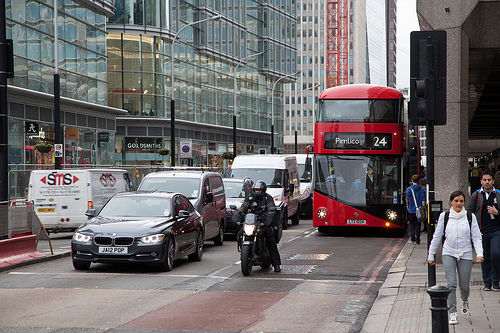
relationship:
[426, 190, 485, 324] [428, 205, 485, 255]
lady wearing jacket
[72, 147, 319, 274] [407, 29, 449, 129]
row parked at traffic light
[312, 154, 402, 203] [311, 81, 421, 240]
window on front of bus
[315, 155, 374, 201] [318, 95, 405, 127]
reflection in window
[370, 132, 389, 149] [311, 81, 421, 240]
number on bus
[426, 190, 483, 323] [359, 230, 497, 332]
lady on sidewalk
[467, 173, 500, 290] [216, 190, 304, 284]
man on bike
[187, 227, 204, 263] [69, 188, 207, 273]
tire of bmw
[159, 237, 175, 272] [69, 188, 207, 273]
tire of bmw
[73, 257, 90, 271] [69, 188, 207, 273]
tire of bmw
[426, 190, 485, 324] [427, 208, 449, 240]
lady wearing back pack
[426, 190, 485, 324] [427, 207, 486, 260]
lady wearing jacket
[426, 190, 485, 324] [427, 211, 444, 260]
lady wearing white jacket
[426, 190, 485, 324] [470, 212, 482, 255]
lady wearing white jacket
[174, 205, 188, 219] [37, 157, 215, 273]
mirror of car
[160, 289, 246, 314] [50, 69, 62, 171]
signs on pole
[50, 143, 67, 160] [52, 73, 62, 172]
signs on pole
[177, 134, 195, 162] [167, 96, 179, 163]
signs on pole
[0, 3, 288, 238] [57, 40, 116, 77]
building with windows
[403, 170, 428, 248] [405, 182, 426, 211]
guy in hoodie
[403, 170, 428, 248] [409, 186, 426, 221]
guy wears bag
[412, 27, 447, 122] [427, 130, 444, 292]
traffic light on pole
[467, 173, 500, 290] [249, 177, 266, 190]
man wears helmet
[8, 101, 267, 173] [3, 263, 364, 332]
store fronts along street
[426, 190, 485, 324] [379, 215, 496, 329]
lady walking along sidewalk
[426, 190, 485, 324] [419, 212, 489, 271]
lady wearing jacket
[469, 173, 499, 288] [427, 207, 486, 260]
man wearing jacket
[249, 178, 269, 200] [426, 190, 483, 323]
head of lady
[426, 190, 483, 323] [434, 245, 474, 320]
lady wearing pants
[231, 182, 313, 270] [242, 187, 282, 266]
man dressed in black